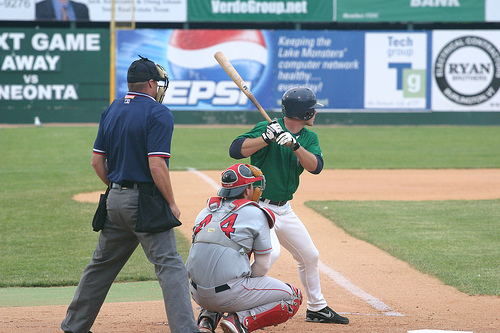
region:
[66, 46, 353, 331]
the umpire, catcher, and batter of a baseball game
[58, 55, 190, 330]
the umpire of a baseball game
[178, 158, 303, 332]
the catcher of a baseball game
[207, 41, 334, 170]
the batter of a baseball game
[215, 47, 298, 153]
hands holding a baseball bat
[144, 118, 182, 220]
the arm of a man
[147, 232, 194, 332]
the leg of a man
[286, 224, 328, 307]
the leg of a man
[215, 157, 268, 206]
the head of a catcher of a baseball game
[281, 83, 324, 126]
a black helmet of a batter of a baseball game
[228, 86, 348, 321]
The baseball player holding bat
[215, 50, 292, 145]
Baseball bat the batter is holding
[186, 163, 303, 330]
Catcher is crouching in a sqatting position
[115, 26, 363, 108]
Advertisement of Pepsi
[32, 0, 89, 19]
A spectator sitting in the stands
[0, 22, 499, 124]
Fence wall at the edge of the field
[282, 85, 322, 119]
Black helmet on batter's head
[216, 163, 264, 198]
Grey and red baseball cap worn inverted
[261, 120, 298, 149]
White gloves worn by the batter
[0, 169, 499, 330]
Brown soil on the field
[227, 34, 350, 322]
A batter on home plate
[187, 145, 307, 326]
A catcher squatting behind batter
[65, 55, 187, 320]
The umpire standing behind catcher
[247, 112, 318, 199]
A dark green shirt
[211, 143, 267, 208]
A orange and gray catchers face mask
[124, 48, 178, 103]
An umpire face mask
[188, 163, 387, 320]
A white chalk line mark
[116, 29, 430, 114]
An advertisement sign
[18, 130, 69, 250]
Green grassy baseball field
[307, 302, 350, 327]
Black and white sports shoe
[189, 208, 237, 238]
The number 44 on the back of the catcher's shirt.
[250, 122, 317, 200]
The green shirt the batter is wearing.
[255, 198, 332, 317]
The white pants the batter is wearing.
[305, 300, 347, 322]
The black sneaker the batter is wearing.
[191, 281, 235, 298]
The black belt on the catcher's pants.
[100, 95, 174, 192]
The blue shirt the umpire has on.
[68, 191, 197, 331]
The gray pants the umpire is wearing.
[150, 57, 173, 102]
The face guard shield the umpire is wearing.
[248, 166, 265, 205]
The face guard shield the catcher is wearing.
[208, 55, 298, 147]
The wooden bat in the batter's hands.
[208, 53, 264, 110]
a baseball bat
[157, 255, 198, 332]
the umpire is wearing grey pants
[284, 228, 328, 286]
white pants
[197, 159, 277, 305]
the catcher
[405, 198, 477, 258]
grass on the baseball field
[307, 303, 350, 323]
black cleats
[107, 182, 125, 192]
umpire is wearing a black belt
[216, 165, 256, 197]
the catcher is wearing a hat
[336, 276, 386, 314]
white line on the baseball field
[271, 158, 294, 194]
a green shirt